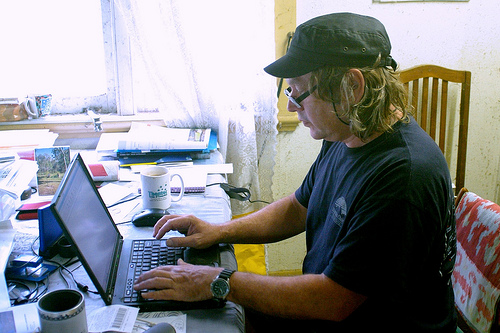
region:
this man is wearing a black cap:
[258, 10, 406, 77]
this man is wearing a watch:
[207, 265, 239, 307]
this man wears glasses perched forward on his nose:
[282, 77, 340, 110]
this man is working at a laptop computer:
[48, 147, 232, 312]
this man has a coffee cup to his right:
[136, 161, 186, 211]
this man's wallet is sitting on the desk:
[12, 194, 60, 224]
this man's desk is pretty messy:
[0, 124, 247, 328]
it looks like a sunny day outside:
[85, 5, 286, 116]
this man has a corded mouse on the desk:
[117, 201, 177, 227]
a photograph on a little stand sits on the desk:
[30, 140, 80, 197]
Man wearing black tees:
[301, 139, 457, 329]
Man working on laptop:
[50, 150, 218, 311]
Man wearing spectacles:
[283, 86, 347, 108]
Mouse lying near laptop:
[131, 209, 170, 225]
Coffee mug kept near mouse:
[138, 168, 185, 208]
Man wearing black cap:
[263, 10, 408, 150]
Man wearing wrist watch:
[206, 269, 237, 303]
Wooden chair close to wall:
[393, 65, 475, 120]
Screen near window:
[135, 0, 265, 110]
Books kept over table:
[119, 125, 221, 161]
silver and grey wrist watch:
[210, 259, 232, 313]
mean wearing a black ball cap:
[261, 10, 411, 146]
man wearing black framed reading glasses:
[272, 17, 410, 145]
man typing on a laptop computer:
[53, 147, 260, 315]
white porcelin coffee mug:
[128, 165, 185, 207]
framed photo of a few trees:
[24, 140, 76, 194]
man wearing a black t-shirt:
[260, 0, 460, 328]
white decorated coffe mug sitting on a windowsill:
[22, 88, 53, 118]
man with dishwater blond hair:
[258, 16, 410, 146]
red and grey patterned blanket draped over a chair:
[458, 175, 496, 332]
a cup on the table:
[141, 168, 165, 196]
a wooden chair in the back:
[423, 65, 465, 107]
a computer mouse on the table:
[131, 214, 158, 224]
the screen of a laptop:
[76, 186, 91, 237]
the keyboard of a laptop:
[137, 250, 159, 260]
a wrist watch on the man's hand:
[211, 274, 227, 294]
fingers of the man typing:
[153, 221, 170, 235]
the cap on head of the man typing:
[283, 38, 350, 61]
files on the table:
[126, 141, 206, 156]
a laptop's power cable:
[70, 273, 87, 288]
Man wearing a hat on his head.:
[244, 5, 433, 93]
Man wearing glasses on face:
[280, 80, 313, 103]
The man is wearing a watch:
[185, 259, 245, 299]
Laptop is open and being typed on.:
[20, 150, 257, 320]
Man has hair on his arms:
[244, 271, 331, 305]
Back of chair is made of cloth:
[465, 188, 493, 330]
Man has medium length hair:
[322, 50, 439, 162]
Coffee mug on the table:
[135, 145, 197, 228]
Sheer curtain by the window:
[137, 10, 312, 172]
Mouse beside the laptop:
[134, 188, 170, 234]